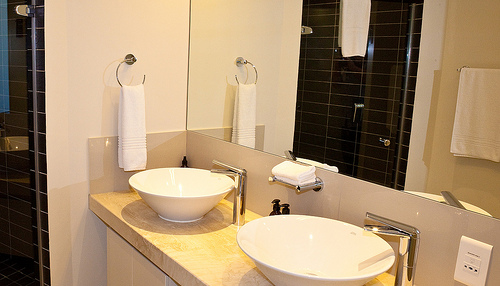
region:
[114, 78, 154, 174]
A white towel is hanging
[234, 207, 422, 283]
A faucet over a sink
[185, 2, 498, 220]
Reflections in the mirror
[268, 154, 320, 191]
Small towels are folded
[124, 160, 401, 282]
Two white sinks on the countertop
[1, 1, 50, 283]
Black tiles on the shower wall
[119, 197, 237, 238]
The sink's shadow on the countertop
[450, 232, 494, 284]
Electric outlet on the wall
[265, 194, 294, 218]
Black tops of two bottles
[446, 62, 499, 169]
A hanging white towel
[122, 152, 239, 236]
this is a bowl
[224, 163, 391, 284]
this is a bowl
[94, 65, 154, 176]
this is a towel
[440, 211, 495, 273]
this is a switch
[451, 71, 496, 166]
this is a towel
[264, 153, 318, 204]
this is a soap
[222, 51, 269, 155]
this is a towel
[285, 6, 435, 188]
this is a door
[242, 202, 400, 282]
the bowl is white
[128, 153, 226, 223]
the bowl is white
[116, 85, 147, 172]
a white hand towel on a rack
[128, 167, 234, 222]
a white bowl on a counter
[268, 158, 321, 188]
a silver soap holder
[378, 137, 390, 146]
handle to a shower door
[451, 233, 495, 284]
a white electrical outlet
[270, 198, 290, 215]
black tips of soap bottles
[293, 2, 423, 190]
black tiles in the shower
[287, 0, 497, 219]
a mirror in a bathroom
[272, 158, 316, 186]
small white towels on a soap holder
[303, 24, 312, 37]
silver hinge to a door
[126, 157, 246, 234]
Round white sink and silver faucet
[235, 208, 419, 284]
Round white sink and silver faucet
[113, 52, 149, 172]
white towel hanging on a silver hook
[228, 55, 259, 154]
reflection of white towel hanging on a silver hook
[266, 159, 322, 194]
white cloth on a silver shelf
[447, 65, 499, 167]
white towel hanging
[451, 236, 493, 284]
white outlet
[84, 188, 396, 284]
bathroom countertop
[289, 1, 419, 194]
white towel hanging over clear shower door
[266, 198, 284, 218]
black top of a soap dispenser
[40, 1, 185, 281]
white towel hanging from curved ring on wall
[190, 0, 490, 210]
mirror panel reflecting dark shower and towel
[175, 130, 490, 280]
backsplash with rack for face towels and outlet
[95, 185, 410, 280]
double sink bowls on yellow stone counter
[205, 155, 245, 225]
split silver pipe as faucet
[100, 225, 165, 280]
tiles under counter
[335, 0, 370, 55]
towel hanging from top of glass door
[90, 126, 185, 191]
backsplash extended to side wall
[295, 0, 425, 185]
glass door with silver handle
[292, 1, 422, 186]
black rectangular tiles with light grout